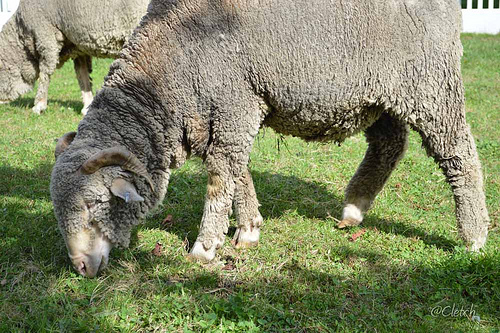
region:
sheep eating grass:
[42, 130, 157, 276]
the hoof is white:
[189, 236, 224, 258]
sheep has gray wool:
[47, 0, 494, 244]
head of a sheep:
[50, 132, 148, 277]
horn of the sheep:
[84, 146, 158, 191]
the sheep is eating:
[0, 0, 147, 112]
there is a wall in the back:
[461, 0, 496, 32]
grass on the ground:
[0, 31, 496, 331]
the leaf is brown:
[155, 242, 162, 252]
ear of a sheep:
[113, 176, 141, 203]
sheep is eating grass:
[43, 3, 496, 325]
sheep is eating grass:
[0, 4, 113, 111]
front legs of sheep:
[181, 144, 271, 266]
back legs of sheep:
[336, 120, 494, 249]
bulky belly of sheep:
[256, 35, 386, 145]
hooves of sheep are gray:
[183, 220, 265, 267]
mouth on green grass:
[58, 232, 118, 288]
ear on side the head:
[106, 173, 151, 211]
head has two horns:
[42, 118, 166, 290]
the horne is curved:
[76, 143, 160, 196]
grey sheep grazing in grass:
[57, 0, 494, 267]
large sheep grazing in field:
[51, 0, 496, 273]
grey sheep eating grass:
[0, 0, 480, 282]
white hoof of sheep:
[188, 238, 220, 271]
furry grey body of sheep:
[240, 0, 399, 137]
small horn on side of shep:
[78, 141, 143, 178]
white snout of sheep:
[78, 221, 117, 271]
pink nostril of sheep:
[73, 259, 89, 276]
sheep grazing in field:
[0, 0, 80, 92]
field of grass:
[154, 274, 369, 331]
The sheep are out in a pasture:
[8, 3, 494, 328]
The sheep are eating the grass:
[18, 5, 488, 322]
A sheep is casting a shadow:
[7, 2, 487, 327]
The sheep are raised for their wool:
[0, 2, 497, 327]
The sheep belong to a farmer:
[23, 5, 495, 317]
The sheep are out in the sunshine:
[17, 6, 482, 329]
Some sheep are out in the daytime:
[20, 3, 490, 328]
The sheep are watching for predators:
[15, 6, 488, 322]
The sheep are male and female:
[7, 6, 494, 307]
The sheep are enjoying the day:
[5, 12, 497, 320]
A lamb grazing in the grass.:
[52, 0, 490, 280]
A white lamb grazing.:
[0, 0, 152, 115]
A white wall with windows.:
[461, 0, 499, 34]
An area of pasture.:
[0, 32, 499, 332]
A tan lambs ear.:
[110, 172, 145, 205]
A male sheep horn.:
[75, 142, 153, 189]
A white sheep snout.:
[66, 225, 114, 277]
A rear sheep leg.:
[388, 50, 490, 254]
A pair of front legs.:
[188, 95, 264, 261]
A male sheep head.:
[47, 129, 159, 279]